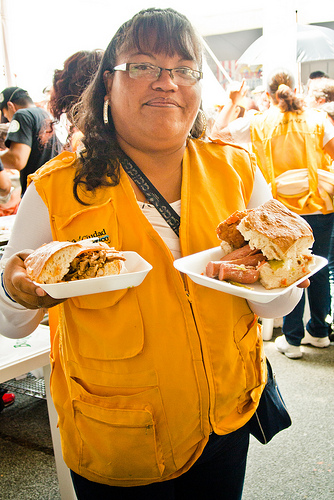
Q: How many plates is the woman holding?
A: Two.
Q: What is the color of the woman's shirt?
A: White.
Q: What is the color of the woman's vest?
A: Yellow.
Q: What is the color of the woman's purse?
A: Black and Yellow.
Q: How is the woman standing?
A: Upright.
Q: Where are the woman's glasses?
A: On her face.